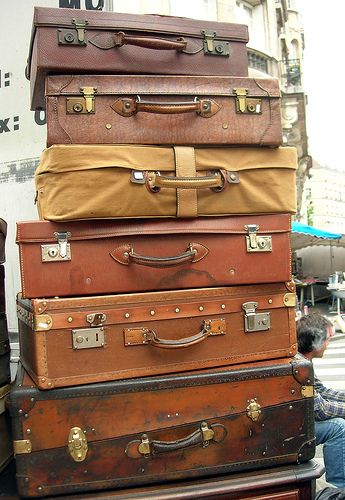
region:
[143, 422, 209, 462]
Brown leather handle on luggage.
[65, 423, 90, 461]
Gold colored latch on suitcase.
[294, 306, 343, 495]
Man sitting in the background.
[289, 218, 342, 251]
Aqua colored canopy top in the background.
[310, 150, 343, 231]
Building in the back ground.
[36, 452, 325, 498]
Wooden table holding suitcases.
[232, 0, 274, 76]
Balcony on the side of the building.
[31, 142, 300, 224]
Tan canvas suitcase in pile.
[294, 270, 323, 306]
Gray table in the background.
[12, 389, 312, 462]
Diagnol opening line on luggage.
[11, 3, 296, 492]
Stacked brown and tan cases.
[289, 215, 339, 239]
A blue and white canopy.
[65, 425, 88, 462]
A gold latch on a brown case.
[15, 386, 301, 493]
A worn brown case.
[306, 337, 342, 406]
White line in the road.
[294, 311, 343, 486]
A man sitting next to the cases.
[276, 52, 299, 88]
A balcony on the building.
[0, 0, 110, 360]
Black letters on a white wall.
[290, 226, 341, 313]
Tables under a canopy.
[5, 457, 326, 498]
The edge of a wooden stand.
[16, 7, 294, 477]
pile of old fashioned suitcases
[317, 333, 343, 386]
white lines of cross walk on street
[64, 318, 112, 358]
metal hooks on suitcase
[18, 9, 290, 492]
pile of six old suitcases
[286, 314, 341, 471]
man wearing blue jeans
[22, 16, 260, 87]
smallest suitcase on top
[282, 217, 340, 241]
green tent with a scalloped edge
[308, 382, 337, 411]
man wearing a blue plaid shirt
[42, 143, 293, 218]
tan fabric suit case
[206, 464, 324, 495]
suitcases piled on brown wooden table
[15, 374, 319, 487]
large vintage suitcase; bottom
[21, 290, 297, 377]
second suitcase on bottom is orange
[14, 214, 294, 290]
third from the bottom tan leather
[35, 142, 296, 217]
fourth from the bottom, yellow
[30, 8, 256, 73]
sixth suitcase is small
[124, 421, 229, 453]
bottom case has old handle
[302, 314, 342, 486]
man sits near suitcases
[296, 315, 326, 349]
man has grey in his hair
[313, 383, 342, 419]
wearing green and white check shirt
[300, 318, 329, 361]
a man sitting down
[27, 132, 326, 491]
stack of suitcases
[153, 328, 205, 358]
handle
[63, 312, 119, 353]
a lock on the suitcase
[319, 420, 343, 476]
blue jeans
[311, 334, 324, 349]
the man has grey hair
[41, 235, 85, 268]
lock on the suitcase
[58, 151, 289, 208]
a yellow suitcase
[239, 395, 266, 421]
lock on the suitcase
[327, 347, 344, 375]
a crosswalk